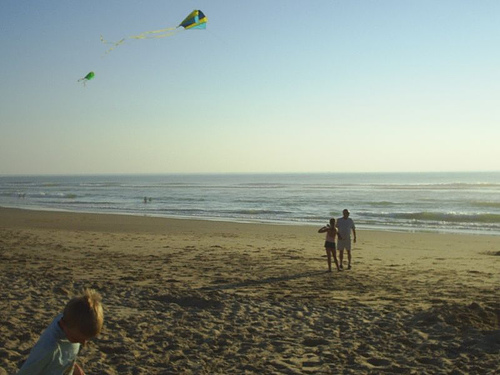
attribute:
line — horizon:
[6, 172, 498, 191]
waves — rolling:
[215, 207, 294, 213]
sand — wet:
[0, 214, 495, 371]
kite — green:
[72, 64, 98, 89]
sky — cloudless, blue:
[237, 35, 499, 167]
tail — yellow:
[94, 27, 186, 48]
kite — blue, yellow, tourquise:
[139, 4, 252, 54]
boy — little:
[36, 266, 130, 373]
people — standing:
[316, 210, 356, 271]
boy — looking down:
[25, 289, 106, 374]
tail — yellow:
[90, 2, 197, 80]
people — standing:
[316, 206, 358, 274]